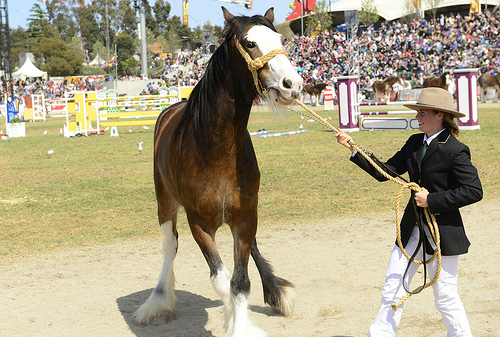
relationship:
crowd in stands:
[257, 28, 483, 89] [291, 9, 482, 92]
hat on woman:
[400, 86, 451, 109] [370, 77, 484, 327]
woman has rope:
[370, 77, 484, 327] [302, 128, 426, 241]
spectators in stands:
[294, 33, 484, 76] [291, 9, 482, 92]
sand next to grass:
[8, 267, 491, 334] [29, 145, 498, 213]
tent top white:
[13, 57, 52, 73] [16, 57, 45, 79]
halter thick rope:
[238, 46, 291, 88] [302, 128, 426, 241]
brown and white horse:
[148, 104, 257, 220] [158, 31, 338, 297]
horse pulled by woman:
[158, 31, 338, 297] [370, 77, 484, 327]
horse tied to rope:
[158, 31, 338, 297] [302, 128, 426, 241]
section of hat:
[401, 103, 463, 120] [400, 86, 451, 109]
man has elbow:
[391, 68, 400, 72] [396, 62, 406, 69]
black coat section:
[437, 132, 453, 148] [401, 103, 463, 120]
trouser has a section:
[446, 311, 469, 333] [401, 103, 463, 120]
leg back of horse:
[153, 212, 184, 315] [158, 31, 338, 297]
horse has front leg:
[158, 31, 338, 297] [153, 212, 184, 315]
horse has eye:
[158, 31, 338, 297] [243, 39, 260, 55]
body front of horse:
[187, 138, 264, 222] [158, 31, 338, 297]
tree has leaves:
[38, 26, 85, 68] [41, 42, 77, 71]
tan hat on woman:
[412, 93, 462, 115] [370, 77, 484, 327]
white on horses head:
[16, 57, 45, 79] [222, 19, 307, 112]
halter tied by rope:
[238, 46, 291, 88] [302, 128, 426, 241]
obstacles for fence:
[73, 101, 168, 147] [337, 78, 361, 133]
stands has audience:
[291, 9, 482, 92] [307, 21, 483, 65]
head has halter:
[230, 17, 300, 86] [238, 46, 291, 88]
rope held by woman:
[302, 128, 426, 241] [370, 77, 484, 327]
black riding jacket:
[437, 132, 453, 148] [359, 132, 480, 248]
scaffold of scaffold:
[398, 8, 495, 25] [398, 8, 495, 25]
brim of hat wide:
[401, 103, 463, 120] [399, 106, 419, 112]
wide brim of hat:
[399, 106, 419, 112] [400, 86, 451, 109]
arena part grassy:
[6, 143, 161, 241] [29, 145, 498, 213]